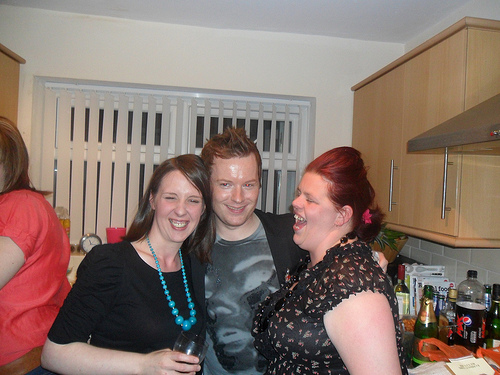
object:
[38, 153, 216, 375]
lady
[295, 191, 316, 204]
eyes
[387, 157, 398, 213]
handle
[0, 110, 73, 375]
woman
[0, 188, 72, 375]
shirt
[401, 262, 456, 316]
books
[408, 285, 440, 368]
champagne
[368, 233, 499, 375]
counter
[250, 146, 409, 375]
lady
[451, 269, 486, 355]
bottle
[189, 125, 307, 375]
man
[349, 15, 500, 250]
cabinet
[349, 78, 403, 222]
cabinet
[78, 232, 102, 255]
clock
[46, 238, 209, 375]
dress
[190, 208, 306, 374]
blazer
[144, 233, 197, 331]
necklace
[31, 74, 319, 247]
blinds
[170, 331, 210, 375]
glass